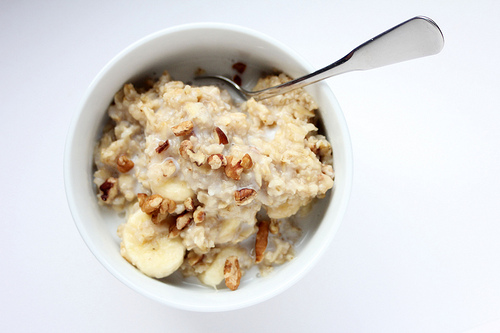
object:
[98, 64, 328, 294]
oatmeal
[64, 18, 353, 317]
bowl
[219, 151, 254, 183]
nut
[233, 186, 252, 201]
nut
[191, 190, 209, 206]
nut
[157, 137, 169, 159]
nut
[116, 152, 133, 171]
nut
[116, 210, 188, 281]
banana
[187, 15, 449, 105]
spoon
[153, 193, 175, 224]
walnut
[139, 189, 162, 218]
walnut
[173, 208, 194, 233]
walnut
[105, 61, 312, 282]
milk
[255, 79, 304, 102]
reflection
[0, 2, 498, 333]
table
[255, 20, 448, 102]
handle